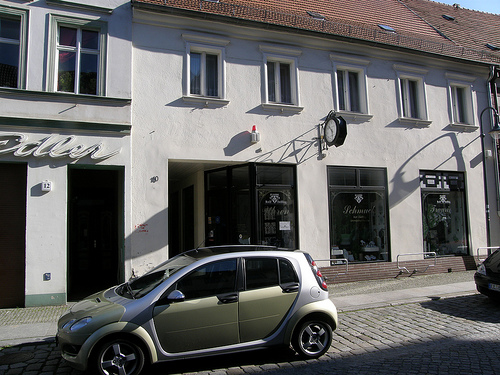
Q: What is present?
A: Cars.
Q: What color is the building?
A: Grey.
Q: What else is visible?
A: A road.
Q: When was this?
A: Daytime.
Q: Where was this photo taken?
A: In front of a business.